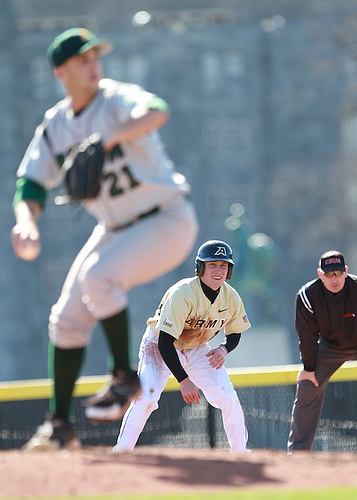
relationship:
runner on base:
[90, 234, 287, 458] [156, 429, 228, 469]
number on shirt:
[102, 162, 151, 211] [145, 286, 252, 349]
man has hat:
[9, 26, 199, 457] [318, 244, 352, 280]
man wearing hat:
[9, 26, 199, 457] [318, 244, 352, 280]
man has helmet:
[9, 26, 199, 457] [45, 24, 120, 77]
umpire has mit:
[276, 247, 357, 484] [54, 158, 117, 213]